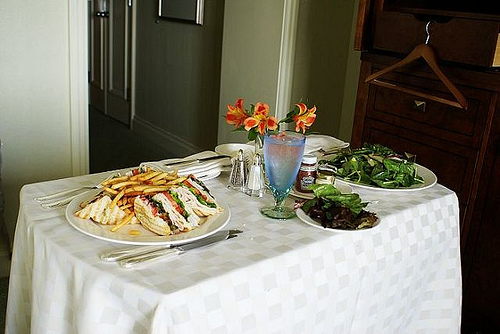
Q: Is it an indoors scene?
A: Yes, it is indoors.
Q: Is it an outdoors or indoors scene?
A: It is indoors.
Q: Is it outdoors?
A: No, it is indoors.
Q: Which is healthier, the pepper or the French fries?
A: The pepper is healthier than the French fries.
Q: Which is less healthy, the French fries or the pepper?
A: The French fries is less healthy than the pepper.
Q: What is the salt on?
A: The salt is on the table.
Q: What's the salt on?
A: The salt is on the table.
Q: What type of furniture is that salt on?
A: The salt is on the table.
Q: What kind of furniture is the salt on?
A: The salt is on the table.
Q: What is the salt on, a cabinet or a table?
A: The salt is on a table.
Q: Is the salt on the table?
A: Yes, the salt is on the table.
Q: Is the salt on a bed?
A: No, the salt is on the table.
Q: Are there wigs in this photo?
A: No, there are no wigs.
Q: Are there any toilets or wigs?
A: No, there are no wigs or toilets.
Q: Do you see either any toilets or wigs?
A: No, there are no wigs or toilets.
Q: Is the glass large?
A: Yes, the glass is large.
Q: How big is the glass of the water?
A: The glass is large.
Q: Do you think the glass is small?
A: No, the glass is large.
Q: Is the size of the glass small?
A: No, the glass is large.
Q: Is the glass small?
A: No, the glass is large.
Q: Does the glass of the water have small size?
A: No, the glass is large.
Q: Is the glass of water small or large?
A: The glass is large.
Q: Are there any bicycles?
A: No, there are no bicycles.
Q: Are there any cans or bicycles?
A: No, there are no bicycles or cans.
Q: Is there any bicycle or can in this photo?
A: No, there are no bicycles or cans.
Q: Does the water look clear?
A: Yes, the water is clear.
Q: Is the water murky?
A: No, the water is clear.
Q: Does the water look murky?
A: No, the water is clear.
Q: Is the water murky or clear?
A: The water is clear.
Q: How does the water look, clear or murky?
A: The water is clear.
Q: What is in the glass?
A: The water is in the glass.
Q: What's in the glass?
A: The water is in the glass.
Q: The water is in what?
A: The water is in the glass.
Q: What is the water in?
A: The water is in the glass.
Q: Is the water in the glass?
A: Yes, the water is in the glass.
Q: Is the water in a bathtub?
A: No, the water is in the glass.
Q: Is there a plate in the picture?
A: Yes, there is a plate.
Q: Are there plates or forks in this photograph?
A: Yes, there is a plate.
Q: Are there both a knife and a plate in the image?
A: Yes, there are both a plate and a knife.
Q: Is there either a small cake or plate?
A: Yes, there is a small plate.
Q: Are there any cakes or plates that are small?
A: Yes, the plate is small.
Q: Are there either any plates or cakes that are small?
A: Yes, the plate is small.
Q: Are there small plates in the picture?
A: Yes, there is a small plate.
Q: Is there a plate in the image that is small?
A: Yes, there is a plate that is small.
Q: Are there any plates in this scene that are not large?
A: Yes, there is a small plate.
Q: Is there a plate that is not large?
A: Yes, there is a small plate.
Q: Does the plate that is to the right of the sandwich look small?
A: Yes, the plate is small.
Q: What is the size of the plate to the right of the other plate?
A: The plate is small.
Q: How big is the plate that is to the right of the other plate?
A: The plate is small.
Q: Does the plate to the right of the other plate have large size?
A: No, the plate is small.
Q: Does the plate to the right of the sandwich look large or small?
A: The plate is small.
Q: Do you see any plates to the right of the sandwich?
A: Yes, there is a plate to the right of the sandwich.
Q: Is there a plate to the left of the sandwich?
A: No, the plate is to the right of the sandwich.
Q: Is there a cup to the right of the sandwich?
A: No, there is a plate to the right of the sandwich.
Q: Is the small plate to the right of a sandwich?
A: Yes, the plate is to the right of a sandwich.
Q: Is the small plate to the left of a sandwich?
A: No, the plate is to the right of a sandwich.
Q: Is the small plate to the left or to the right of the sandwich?
A: The plate is to the right of the sandwich.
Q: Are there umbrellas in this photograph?
A: No, there are no umbrellas.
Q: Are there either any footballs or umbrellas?
A: No, there are no umbrellas or footballs.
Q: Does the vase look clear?
A: Yes, the vase is clear.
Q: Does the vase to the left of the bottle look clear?
A: Yes, the vase is clear.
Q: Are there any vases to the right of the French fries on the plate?
A: Yes, there is a vase to the right of the French fries.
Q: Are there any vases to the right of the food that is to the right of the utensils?
A: Yes, there is a vase to the right of the French fries.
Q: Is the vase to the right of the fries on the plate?
A: Yes, the vase is to the right of the French fries.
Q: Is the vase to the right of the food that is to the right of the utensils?
A: Yes, the vase is to the right of the French fries.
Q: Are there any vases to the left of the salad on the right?
A: Yes, there is a vase to the left of the salad.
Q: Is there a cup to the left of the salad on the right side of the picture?
A: No, there is a vase to the left of the salad.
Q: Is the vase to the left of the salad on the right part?
A: Yes, the vase is to the left of the salad.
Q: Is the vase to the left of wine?
A: No, the vase is to the left of the salad.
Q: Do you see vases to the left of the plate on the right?
A: Yes, there is a vase to the left of the plate.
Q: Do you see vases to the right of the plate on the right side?
A: No, the vase is to the left of the plate.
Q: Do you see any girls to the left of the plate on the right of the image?
A: No, there is a vase to the left of the plate.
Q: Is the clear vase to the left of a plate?
A: Yes, the vase is to the left of a plate.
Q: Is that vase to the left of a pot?
A: No, the vase is to the left of a plate.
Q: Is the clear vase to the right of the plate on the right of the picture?
A: No, the vase is to the left of the plate.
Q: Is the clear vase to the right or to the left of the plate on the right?
A: The vase is to the left of the plate.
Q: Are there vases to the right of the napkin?
A: Yes, there is a vase to the right of the napkin.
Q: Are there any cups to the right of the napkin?
A: No, there is a vase to the right of the napkin.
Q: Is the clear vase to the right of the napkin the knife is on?
A: Yes, the vase is to the right of the napkin.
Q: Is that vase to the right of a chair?
A: No, the vase is to the right of the napkin.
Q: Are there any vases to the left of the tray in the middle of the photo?
A: Yes, there is a vase to the left of the tray.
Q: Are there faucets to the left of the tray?
A: No, there is a vase to the left of the tray.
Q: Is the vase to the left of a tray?
A: Yes, the vase is to the left of a tray.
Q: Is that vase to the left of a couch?
A: No, the vase is to the left of a tray.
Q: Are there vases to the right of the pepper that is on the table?
A: Yes, there is a vase to the right of the pepper.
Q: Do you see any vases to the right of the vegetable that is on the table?
A: Yes, there is a vase to the right of the pepper.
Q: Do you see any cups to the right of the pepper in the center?
A: No, there is a vase to the right of the pepper.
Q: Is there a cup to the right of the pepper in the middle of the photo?
A: No, there is a vase to the right of the pepper.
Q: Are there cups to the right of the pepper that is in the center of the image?
A: No, there is a vase to the right of the pepper.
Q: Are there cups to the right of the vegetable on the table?
A: No, there is a vase to the right of the pepper.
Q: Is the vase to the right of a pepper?
A: Yes, the vase is to the right of a pepper.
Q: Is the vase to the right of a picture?
A: No, the vase is to the right of a pepper.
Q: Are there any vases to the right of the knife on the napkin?
A: Yes, there is a vase to the right of the knife.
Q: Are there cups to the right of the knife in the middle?
A: No, there is a vase to the right of the knife.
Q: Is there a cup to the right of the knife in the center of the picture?
A: No, there is a vase to the right of the knife.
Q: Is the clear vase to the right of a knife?
A: Yes, the vase is to the right of a knife.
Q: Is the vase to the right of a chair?
A: No, the vase is to the right of a knife.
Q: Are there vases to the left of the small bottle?
A: Yes, there is a vase to the left of the bottle.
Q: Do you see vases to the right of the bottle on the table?
A: No, the vase is to the left of the bottle.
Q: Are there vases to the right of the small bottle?
A: No, the vase is to the left of the bottle.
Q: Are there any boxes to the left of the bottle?
A: No, there is a vase to the left of the bottle.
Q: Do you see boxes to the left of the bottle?
A: No, there is a vase to the left of the bottle.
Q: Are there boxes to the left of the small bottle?
A: No, there is a vase to the left of the bottle.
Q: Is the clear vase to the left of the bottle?
A: Yes, the vase is to the left of the bottle.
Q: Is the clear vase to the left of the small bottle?
A: Yes, the vase is to the left of the bottle.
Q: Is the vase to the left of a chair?
A: No, the vase is to the left of the bottle.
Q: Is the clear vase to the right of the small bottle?
A: No, the vase is to the left of the bottle.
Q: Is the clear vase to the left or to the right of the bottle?
A: The vase is to the left of the bottle.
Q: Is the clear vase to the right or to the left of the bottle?
A: The vase is to the left of the bottle.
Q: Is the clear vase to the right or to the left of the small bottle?
A: The vase is to the left of the bottle.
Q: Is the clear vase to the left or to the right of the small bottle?
A: The vase is to the left of the bottle.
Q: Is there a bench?
A: No, there are no benches.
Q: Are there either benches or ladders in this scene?
A: No, there are no benches or ladders.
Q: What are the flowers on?
A: The flowers are on the table.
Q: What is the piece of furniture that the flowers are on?
A: The piece of furniture is a table.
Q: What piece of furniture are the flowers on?
A: The flowers are on the table.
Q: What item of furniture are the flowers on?
A: The flowers are on the table.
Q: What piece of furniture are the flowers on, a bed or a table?
A: The flowers are on a table.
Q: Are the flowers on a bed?
A: No, the flowers are on a table.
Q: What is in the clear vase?
A: The flowers are in the vase.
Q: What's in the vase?
A: The flowers are in the vase.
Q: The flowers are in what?
A: The flowers are in the vase.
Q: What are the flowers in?
A: The flowers are in the vase.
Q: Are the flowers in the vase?
A: Yes, the flowers are in the vase.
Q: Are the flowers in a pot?
A: No, the flowers are in the vase.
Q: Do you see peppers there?
A: Yes, there is a pepper.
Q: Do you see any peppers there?
A: Yes, there is a pepper.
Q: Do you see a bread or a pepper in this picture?
A: Yes, there is a pepper.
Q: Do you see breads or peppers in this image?
A: Yes, there is a pepper.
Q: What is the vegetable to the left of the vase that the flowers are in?
A: The vegetable is a pepper.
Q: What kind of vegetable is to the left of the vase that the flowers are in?
A: The vegetable is a pepper.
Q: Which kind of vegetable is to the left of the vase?
A: The vegetable is a pepper.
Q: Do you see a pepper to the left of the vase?
A: Yes, there is a pepper to the left of the vase.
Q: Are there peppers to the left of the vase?
A: Yes, there is a pepper to the left of the vase.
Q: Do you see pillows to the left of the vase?
A: No, there is a pepper to the left of the vase.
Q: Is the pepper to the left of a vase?
A: Yes, the pepper is to the left of a vase.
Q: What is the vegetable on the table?
A: The vegetable is a pepper.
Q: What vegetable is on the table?
A: The vegetable is a pepper.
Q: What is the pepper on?
A: The pepper is on the table.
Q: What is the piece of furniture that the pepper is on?
A: The piece of furniture is a table.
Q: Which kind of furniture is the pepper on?
A: The pepper is on the table.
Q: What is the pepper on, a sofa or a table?
A: The pepper is on a table.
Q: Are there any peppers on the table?
A: Yes, there is a pepper on the table.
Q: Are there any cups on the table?
A: No, there is a pepper on the table.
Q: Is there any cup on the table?
A: No, there is a pepper on the table.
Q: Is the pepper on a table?
A: Yes, the pepper is on a table.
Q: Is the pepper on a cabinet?
A: No, the pepper is on a table.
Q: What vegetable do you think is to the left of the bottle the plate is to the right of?
A: The vegetable is a pepper.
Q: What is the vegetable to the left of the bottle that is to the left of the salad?
A: The vegetable is a pepper.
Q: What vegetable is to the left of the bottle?
A: The vegetable is a pepper.